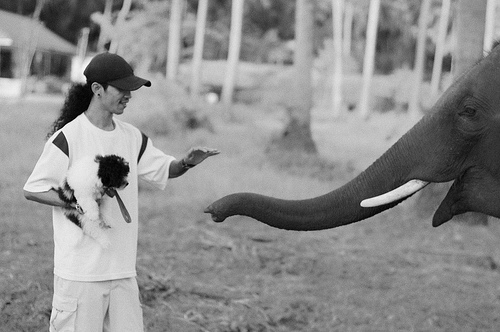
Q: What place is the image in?
A: It is at the yard.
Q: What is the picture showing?
A: It is showing a yard.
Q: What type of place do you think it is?
A: It is a yard.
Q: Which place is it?
A: It is a yard.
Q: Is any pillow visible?
A: No, there are no pillows.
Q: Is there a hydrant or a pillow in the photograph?
A: No, there are no pillows or fire hydrants.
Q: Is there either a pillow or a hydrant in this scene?
A: No, there are no pillows or fire hydrants.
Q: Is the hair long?
A: Yes, the hair is long.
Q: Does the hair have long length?
A: Yes, the hair is long.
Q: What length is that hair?
A: The hair is long.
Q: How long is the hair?
A: The hair is long.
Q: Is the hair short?
A: No, the hair is long.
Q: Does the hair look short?
A: No, the hair is long.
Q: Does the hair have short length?
A: No, the hair is long.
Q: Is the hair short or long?
A: The hair is long.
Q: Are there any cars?
A: No, there are no cars.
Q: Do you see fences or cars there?
A: No, there are no cars or fences.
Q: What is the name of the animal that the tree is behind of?
A: The animal is an elephant.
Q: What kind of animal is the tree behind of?
A: The tree is behind the elephant.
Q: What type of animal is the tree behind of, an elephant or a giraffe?
A: The tree is behind an elephant.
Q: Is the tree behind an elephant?
A: Yes, the tree is behind an elephant.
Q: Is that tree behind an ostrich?
A: No, the tree is behind an elephant.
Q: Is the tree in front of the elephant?
A: No, the tree is behind the elephant.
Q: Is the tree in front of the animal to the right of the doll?
A: No, the tree is behind the elephant.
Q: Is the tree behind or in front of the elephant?
A: The tree is behind the elephant.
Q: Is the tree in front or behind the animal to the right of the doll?
A: The tree is behind the elephant.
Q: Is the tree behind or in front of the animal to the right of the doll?
A: The tree is behind the elephant.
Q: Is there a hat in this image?
A: Yes, there is a hat.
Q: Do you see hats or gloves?
A: Yes, there is a hat.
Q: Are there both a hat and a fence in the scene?
A: No, there is a hat but no fences.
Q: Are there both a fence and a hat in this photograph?
A: No, there is a hat but no fences.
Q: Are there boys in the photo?
A: No, there are no boys.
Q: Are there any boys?
A: No, there are no boys.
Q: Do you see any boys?
A: No, there are no boys.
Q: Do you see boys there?
A: No, there are no boys.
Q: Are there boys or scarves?
A: No, there are no boys or scarves.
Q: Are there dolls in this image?
A: Yes, there is a doll.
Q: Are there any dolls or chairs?
A: Yes, there is a doll.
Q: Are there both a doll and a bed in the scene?
A: No, there is a doll but no beds.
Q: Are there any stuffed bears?
A: No, there are no stuffed bears.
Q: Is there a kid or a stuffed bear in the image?
A: No, there are no stuffed bears or children.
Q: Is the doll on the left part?
A: Yes, the doll is on the left of the image.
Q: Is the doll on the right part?
A: No, the doll is on the left of the image.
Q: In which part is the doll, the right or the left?
A: The doll is on the left of the image.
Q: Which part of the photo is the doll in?
A: The doll is on the left of the image.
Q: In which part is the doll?
A: The doll is on the left of the image.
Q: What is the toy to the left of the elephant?
A: The toy is a doll.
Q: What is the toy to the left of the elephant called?
A: The toy is a doll.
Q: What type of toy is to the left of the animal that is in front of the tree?
A: The toy is a doll.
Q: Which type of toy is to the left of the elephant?
A: The toy is a doll.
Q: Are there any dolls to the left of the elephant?
A: Yes, there is a doll to the left of the elephant.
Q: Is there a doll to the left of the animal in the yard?
A: Yes, there is a doll to the left of the elephant.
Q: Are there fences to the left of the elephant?
A: No, there is a doll to the left of the elephant.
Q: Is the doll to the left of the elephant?
A: Yes, the doll is to the left of the elephant.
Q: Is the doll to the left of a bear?
A: No, the doll is to the left of the elephant.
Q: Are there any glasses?
A: No, there are no glasses.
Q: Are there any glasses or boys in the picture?
A: No, there are no glasses or boys.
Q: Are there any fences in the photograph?
A: No, there are no fences.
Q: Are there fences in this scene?
A: No, there are no fences.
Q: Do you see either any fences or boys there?
A: No, there are no fences or boys.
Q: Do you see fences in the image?
A: No, there are no fences.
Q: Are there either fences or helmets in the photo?
A: No, there are no fences or helmets.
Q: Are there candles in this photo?
A: No, there are no candles.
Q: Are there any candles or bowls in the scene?
A: No, there are no candles or bowls.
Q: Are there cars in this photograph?
A: No, there are no cars.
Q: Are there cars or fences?
A: No, there are no cars or fences.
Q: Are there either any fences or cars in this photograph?
A: No, there are no cars or fences.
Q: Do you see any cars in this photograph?
A: No, there are no cars.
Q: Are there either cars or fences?
A: No, there are no cars or fences.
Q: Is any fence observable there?
A: No, there are no fences.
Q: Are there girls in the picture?
A: No, there are no girls.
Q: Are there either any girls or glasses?
A: No, there are no girls or glasses.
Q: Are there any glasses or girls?
A: No, there are no girls or glasses.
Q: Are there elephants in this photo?
A: Yes, there is an elephant.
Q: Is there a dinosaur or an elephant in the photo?
A: Yes, there is an elephant.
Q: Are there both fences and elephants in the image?
A: No, there is an elephant but no fences.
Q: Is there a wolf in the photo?
A: No, there are no wolves.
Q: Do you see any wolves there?
A: No, there are no wolves.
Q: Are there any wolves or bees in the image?
A: No, there are no wolves or bees.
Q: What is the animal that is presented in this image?
A: The animal is an elephant.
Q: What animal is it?
A: The animal is an elephant.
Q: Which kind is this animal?
A: This is an elephant.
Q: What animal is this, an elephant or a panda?
A: This is an elephant.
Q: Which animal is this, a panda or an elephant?
A: This is an elephant.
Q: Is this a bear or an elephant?
A: This is an elephant.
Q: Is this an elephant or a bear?
A: This is an elephant.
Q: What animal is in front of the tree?
A: The elephant is in front of the tree.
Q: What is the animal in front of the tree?
A: The animal is an elephant.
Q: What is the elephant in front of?
A: The elephant is in front of the tree.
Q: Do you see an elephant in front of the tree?
A: Yes, there is an elephant in front of the tree.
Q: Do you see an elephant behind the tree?
A: No, the elephant is in front of the tree.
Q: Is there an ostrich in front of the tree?
A: No, there is an elephant in front of the tree.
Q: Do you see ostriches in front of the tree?
A: No, there is an elephant in front of the tree.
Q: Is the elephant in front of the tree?
A: Yes, the elephant is in front of the tree.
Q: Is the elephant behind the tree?
A: No, the elephant is in front of the tree.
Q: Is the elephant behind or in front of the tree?
A: The elephant is in front of the tree.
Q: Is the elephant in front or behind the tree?
A: The elephant is in front of the tree.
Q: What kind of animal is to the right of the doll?
A: The animal is an elephant.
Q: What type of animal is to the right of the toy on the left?
A: The animal is an elephant.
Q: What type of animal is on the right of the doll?
A: The animal is an elephant.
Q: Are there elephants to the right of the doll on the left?
A: Yes, there is an elephant to the right of the doll.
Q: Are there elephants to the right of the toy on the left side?
A: Yes, there is an elephant to the right of the doll.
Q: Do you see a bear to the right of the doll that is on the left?
A: No, there is an elephant to the right of the doll.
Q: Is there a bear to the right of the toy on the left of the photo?
A: No, there is an elephant to the right of the doll.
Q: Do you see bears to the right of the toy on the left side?
A: No, there is an elephant to the right of the doll.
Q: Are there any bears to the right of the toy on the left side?
A: No, there is an elephant to the right of the doll.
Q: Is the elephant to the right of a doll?
A: Yes, the elephant is to the right of a doll.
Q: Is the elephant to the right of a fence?
A: No, the elephant is to the right of a doll.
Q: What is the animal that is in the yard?
A: The animal is an elephant.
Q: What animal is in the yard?
A: The animal is an elephant.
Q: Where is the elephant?
A: The elephant is in the yard.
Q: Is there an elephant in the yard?
A: Yes, there is an elephant in the yard.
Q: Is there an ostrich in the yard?
A: No, there is an elephant in the yard.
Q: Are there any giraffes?
A: No, there are no giraffes.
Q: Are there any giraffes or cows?
A: No, there are no giraffes or cows.